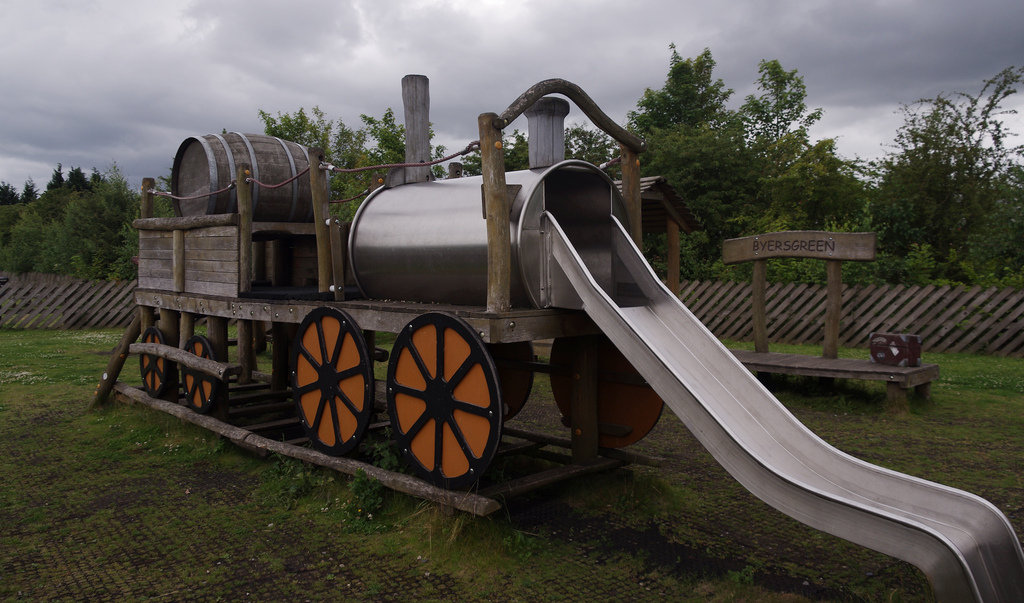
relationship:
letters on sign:
[719, 232, 875, 261] [720, 224, 883, 268]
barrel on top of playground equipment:
[147, 111, 334, 232] [96, 74, 1023, 600]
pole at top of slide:
[468, 119, 516, 322] [539, 206, 1023, 600]